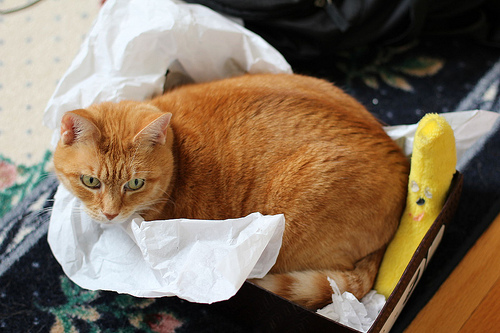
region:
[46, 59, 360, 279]
The cat is curled up.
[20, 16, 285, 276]
The cat is sitting in a box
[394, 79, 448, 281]
The cat has a toy banana.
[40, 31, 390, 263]
The cat is orange.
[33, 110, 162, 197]
The cat has green eyes.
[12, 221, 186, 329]
The flowers on the carpet are pink.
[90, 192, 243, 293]
The tissue paper is white.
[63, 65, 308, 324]
The cat is sitting on the tissue paper.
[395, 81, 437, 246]
The banana is yellow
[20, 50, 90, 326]
The box is on a carpet.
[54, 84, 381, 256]
the cat is orange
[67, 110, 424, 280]
the cat is lying down in a box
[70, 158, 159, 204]
cat's eyes are green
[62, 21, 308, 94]
the paper is white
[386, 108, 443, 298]
the toy is a banana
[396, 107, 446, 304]
banana toy is yellow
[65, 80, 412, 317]
cat is on the box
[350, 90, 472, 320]
banana toy on the box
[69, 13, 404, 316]
cat is on paper tissue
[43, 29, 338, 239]
the tissue is in the box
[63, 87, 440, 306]
The cat is sitting.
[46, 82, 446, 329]
The cat is sitting in a box.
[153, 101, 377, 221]
The cat is orange.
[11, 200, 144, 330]
There is a carpet under the box.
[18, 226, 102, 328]
The carpet under the box is floral.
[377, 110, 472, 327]
The cat has a toy banana.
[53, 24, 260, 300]
The cat is sitting on tissue paper.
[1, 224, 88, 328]
The carpet under that cat is blue, green and pink.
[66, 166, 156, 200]
The cat has green eyes.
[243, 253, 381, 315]
The cat has a striped tail.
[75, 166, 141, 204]
the cats green eyes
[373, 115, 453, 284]
a banana by the cat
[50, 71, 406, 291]
a tabby cat on the bed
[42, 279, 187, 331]
the flower design on the blanket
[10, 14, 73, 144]
a white sheet with blue spots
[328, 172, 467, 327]
the end of a brown box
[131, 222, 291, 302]
a white sheet of paper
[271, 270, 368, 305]
an orange and white cat tail.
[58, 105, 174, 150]
the cat ears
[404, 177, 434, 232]
the face of the toy banana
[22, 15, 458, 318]
cat laying in a shoe box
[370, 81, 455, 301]
fuzzy banana toy with face next to cat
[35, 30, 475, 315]
white tissue paper lining the box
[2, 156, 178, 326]
flower pattern in the rug of green and pink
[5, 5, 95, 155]
blue dots on cream background on rug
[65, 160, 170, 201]
yellowish green eyes with dark pupils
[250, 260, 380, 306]
thick white stripes on cat's tail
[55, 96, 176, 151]
cat ears filled with white fur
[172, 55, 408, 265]
round body covered with honey colored fur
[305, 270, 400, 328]
scrunched up paper in the corner of box